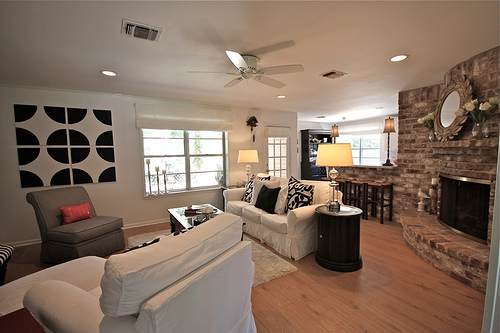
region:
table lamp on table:
[271, 130, 372, 250]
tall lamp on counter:
[368, 100, 408, 191]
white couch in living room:
[221, 165, 335, 272]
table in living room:
[148, 182, 260, 249]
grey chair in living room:
[1, 174, 151, 263]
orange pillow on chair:
[53, 198, 120, 224]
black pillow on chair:
[250, 172, 288, 227]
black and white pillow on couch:
[277, 163, 315, 225]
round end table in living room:
[305, 188, 387, 278]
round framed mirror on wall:
[413, 59, 488, 146]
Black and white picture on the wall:
[3, 94, 68, 149]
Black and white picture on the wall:
[63, 97, 122, 147]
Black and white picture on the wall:
[66, 142, 126, 185]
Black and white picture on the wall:
[8, 146, 74, 189]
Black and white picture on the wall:
[8, 98, 129, 190]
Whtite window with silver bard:
[118, 96, 234, 197]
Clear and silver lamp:
[305, 132, 358, 219]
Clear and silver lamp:
[235, 144, 267, 200]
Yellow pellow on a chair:
[55, 197, 105, 234]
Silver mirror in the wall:
[425, 70, 473, 145]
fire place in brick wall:
[432, 165, 493, 243]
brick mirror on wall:
[429, 78, 469, 139]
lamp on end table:
[315, 140, 356, 214]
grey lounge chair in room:
[28, 185, 123, 257]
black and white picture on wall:
[12, 104, 115, 188]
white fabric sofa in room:
[223, 176, 341, 256]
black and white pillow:
[286, 175, 313, 214]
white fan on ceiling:
[213, 48, 303, 89]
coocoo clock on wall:
[246, 115, 258, 132]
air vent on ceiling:
[120, 18, 161, 43]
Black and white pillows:
[236, 166, 317, 214]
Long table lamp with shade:
[377, 110, 397, 170]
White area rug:
[122, 210, 300, 296]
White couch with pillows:
[217, 162, 352, 265]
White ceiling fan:
[180, 40, 307, 106]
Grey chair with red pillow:
[20, 178, 131, 261]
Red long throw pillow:
[55, 200, 95, 223]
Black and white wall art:
[7, 97, 118, 185]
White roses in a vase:
[447, 87, 494, 139]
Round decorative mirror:
[425, 68, 472, 144]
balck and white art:
[9, 94, 121, 191]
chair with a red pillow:
[23, 181, 125, 258]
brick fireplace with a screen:
[427, 150, 490, 285]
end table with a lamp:
[308, 138, 365, 273]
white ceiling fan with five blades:
[186, 43, 304, 95]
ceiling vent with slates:
[115, 13, 164, 48]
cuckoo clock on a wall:
[243, 111, 262, 146]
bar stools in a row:
[338, 169, 393, 211]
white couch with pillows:
[226, 171, 333, 253]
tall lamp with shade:
[378, 113, 395, 170]